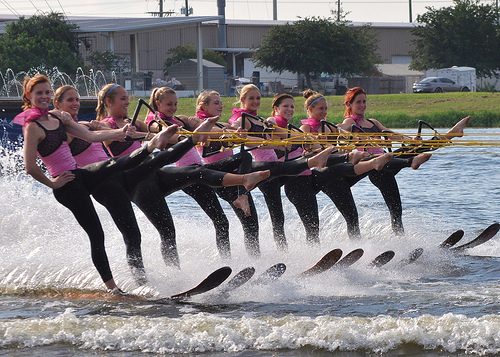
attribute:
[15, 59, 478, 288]
woman — water skiing, grouped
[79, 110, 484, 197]
foot — lifted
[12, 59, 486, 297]
women — standing, water skiing, wearing pink scarf, wearing pink and black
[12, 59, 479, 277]
girls — smiling, waterskiing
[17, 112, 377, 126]
scarves — pink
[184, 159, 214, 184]
knee — bent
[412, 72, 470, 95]
car — silver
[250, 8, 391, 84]
tree — green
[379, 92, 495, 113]
grass — green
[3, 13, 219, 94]
cover — metal, large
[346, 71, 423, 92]
fence — wooden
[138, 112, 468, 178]
feet — bare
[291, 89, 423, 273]
woman — blue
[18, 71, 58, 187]
woman — wearing pink scarf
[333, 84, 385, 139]
woman — wearing pink scarf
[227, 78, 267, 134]
woman — wearing pink scarf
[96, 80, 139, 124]
woman — wearing pink scarf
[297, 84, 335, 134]
woman — wearing pink scarf